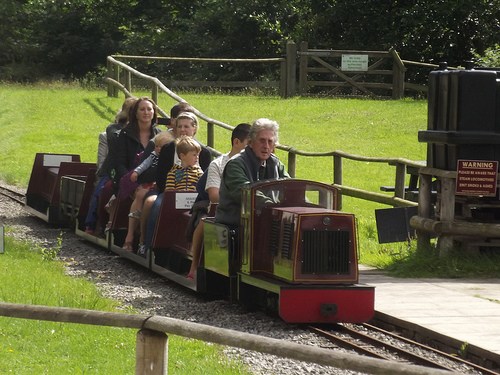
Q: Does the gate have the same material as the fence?
A: Yes, both the gate and the fence are made of wood.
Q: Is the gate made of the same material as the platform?
A: Yes, both the gate and the platform are made of wood.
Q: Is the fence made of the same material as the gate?
A: Yes, both the fence and the gate are made of wood.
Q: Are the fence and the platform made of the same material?
A: Yes, both the fence and the platform are made of wood.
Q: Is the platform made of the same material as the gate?
A: Yes, both the platform and the gate are made of wood.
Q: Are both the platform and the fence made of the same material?
A: Yes, both the platform and the fence are made of wood.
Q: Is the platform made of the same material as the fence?
A: Yes, both the platform and the fence are made of wood.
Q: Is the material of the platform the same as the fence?
A: Yes, both the platform and the fence are made of wood.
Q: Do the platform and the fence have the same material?
A: Yes, both the platform and the fence are made of wood.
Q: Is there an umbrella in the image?
A: No, there are no umbrellas.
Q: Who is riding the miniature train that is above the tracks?
A: The people are riding the train.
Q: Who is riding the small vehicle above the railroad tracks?
A: The people are riding the train.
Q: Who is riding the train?
A: The people are riding the train.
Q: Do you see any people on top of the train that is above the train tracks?
A: Yes, there are people on top of the train.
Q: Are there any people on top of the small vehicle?
A: Yes, there are people on top of the train.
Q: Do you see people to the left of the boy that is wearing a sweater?
A: Yes, there are people to the left of the boy.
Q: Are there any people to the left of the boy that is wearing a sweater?
A: Yes, there are people to the left of the boy.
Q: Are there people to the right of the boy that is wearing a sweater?
A: No, the people are to the left of the boy.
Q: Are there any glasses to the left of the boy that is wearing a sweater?
A: No, there are people to the left of the boy.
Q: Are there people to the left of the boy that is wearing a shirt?
A: Yes, there are people to the left of the boy.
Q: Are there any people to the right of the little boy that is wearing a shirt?
A: No, the people are to the left of the boy.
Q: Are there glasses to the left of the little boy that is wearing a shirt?
A: No, there are people to the left of the boy.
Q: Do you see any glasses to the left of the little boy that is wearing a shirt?
A: No, there are people to the left of the boy.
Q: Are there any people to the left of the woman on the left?
A: Yes, there are people to the left of the woman.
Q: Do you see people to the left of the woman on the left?
A: Yes, there are people to the left of the woman.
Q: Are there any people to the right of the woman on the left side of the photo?
A: No, the people are to the left of the woman.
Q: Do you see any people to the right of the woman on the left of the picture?
A: No, the people are to the left of the woman.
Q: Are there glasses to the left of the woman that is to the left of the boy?
A: No, there are people to the left of the woman.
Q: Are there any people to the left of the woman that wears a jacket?
A: Yes, there are people to the left of the woman.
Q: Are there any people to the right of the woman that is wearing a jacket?
A: No, the people are to the left of the woman.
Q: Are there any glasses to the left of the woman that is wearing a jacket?
A: No, there are people to the left of the woman.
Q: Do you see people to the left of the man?
A: Yes, there are people to the left of the man.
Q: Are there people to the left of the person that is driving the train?
A: Yes, there are people to the left of the man.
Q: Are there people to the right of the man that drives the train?
A: No, the people are to the left of the man.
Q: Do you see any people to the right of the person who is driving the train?
A: No, the people are to the left of the man.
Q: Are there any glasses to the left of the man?
A: No, there are people to the left of the man.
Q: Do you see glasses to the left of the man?
A: No, there are people to the left of the man.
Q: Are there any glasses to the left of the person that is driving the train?
A: No, there are people to the left of the man.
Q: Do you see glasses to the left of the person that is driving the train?
A: No, there are people to the left of the man.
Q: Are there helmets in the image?
A: No, there are no helmets.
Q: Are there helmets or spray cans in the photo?
A: No, there are no helmets or spray cans.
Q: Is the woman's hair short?
A: No, the hair is long.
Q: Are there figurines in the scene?
A: No, there are no figurines.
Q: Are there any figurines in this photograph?
A: No, there are no figurines.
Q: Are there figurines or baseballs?
A: No, there are no figurines or baseballs.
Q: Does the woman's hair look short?
A: Yes, the hair is short.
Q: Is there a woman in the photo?
A: Yes, there is a woman.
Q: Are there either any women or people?
A: Yes, there is a woman.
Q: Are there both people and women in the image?
A: Yes, there are both a woman and people.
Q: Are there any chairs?
A: No, there are no chairs.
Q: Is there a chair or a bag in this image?
A: No, there are no chairs or bags.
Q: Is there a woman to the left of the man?
A: Yes, there is a woman to the left of the man.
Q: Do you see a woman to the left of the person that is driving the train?
A: Yes, there is a woman to the left of the man.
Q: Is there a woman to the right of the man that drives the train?
A: No, the woman is to the left of the man.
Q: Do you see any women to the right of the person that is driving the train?
A: No, the woman is to the left of the man.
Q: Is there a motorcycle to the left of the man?
A: No, there is a woman to the left of the man.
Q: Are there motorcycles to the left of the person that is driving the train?
A: No, there is a woman to the left of the man.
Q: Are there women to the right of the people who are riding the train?
A: Yes, there is a woman to the right of the people.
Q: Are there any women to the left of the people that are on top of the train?
A: No, the woman is to the right of the people.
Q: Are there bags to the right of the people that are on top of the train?
A: No, there is a woman to the right of the people.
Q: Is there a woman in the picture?
A: Yes, there is a woman.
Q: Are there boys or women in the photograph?
A: Yes, there is a woman.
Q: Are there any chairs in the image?
A: No, there are no chairs.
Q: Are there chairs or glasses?
A: No, there are no chairs or glasses.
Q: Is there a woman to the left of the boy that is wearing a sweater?
A: Yes, there is a woman to the left of the boy.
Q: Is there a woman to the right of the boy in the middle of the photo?
A: No, the woman is to the left of the boy.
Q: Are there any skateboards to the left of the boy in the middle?
A: No, there is a woman to the left of the boy.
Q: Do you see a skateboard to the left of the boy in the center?
A: No, there is a woman to the left of the boy.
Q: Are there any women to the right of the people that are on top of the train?
A: Yes, there is a woman to the right of the people.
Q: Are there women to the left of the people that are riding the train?
A: No, the woman is to the right of the people.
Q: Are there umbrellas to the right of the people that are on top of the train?
A: No, there is a woman to the right of the people.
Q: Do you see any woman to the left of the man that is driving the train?
A: Yes, there is a woman to the left of the man.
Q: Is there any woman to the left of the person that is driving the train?
A: Yes, there is a woman to the left of the man.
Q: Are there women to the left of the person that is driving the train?
A: Yes, there is a woman to the left of the man.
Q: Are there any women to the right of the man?
A: No, the woman is to the left of the man.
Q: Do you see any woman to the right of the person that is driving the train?
A: No, the woman is to the left of the man.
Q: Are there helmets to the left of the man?
A: No, there is a woman to the left of the man.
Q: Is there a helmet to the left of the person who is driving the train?
A: No, there is a woman to the left of the man.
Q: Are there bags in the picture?
A: No, there are no bags.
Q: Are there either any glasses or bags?
A: No, there are no bags or glasses.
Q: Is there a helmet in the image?
A: No, there are no helmets.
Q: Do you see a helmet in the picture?
A: No, there are no helmets.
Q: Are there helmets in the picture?
A: No, there are no helmets.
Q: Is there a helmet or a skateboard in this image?
A: No, there are no helmets or skateboards.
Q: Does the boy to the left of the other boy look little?
A: Yes, the boy is little.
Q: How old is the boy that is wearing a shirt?
A: The boy is little.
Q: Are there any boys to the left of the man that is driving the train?
A: Yes, there is a boy to the left of the man.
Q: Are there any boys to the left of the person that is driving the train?
A: Yes, there is a boy to the left of the man.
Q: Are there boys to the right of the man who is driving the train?
A: No, the boy is to the left of the man.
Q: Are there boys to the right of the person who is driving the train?
A: No, the boy is to the left of the man.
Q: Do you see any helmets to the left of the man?
A: No, there is a boy to the left of the man.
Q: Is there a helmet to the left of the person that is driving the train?
A: No, there is a boy to the left of the man.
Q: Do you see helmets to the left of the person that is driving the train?
A: No, there is a boy to the left of the man.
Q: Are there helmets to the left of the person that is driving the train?
A: No, there is a boy to the left of the man.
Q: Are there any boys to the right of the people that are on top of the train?
A: Yes, there is a boy to the right of the people.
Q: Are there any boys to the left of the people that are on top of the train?
A: No, the boy is to the right of the people.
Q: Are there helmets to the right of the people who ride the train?
A: No, there is a boy to the right of the people.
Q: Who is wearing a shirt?
A: The boy is wearing a shirt.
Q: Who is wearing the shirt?
A: The boy is wearing a shirt.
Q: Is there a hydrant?
A: No, there are no fire hydrants.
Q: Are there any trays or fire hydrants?
A: No, there are no fire hydrants or trays.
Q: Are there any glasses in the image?
A: No, there are no glasses.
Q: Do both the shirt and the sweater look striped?
A: Yes, both the shirt and the sweater are striped.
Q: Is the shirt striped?
A: Yes, the shirt is striped.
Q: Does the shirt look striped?
A: Yes, the shirt is striped.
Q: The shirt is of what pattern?
A: The shirt is striped.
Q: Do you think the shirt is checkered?
A: No, the shirt is striped.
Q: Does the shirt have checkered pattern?
A: No, the shirt is striped.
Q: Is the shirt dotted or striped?
A: The shirt is striped.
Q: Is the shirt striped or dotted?
A: The shirt is striped.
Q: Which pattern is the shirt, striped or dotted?
A: The shirt is striped.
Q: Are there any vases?
A: No, there are no vases.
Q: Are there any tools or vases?
A: No, there are no vases or tools.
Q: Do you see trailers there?
A: No, there are no trailers.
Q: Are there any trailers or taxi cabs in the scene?
A: No, there are no trailers or taxi cabs.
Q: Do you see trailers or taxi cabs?
A: No, there are no trailers or taxi cabs.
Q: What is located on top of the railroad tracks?
A: The engine is on top of the railroad tracks.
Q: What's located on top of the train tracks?
A: The engine is on top of the railroad tracks.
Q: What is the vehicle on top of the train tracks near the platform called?
A: The vehicle is a locomotive.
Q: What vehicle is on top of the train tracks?
A: The vehicle is a locomotive.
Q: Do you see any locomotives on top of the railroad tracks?
A: Yes, there is a locomotive on top of the railroad tracks.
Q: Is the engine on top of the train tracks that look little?
A: Yes, the engine is on top of the tracks.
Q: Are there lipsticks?
A: No, there are no lipsticks.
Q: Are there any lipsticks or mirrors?
A: No, there are no lipsticks or mirrors.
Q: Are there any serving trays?
A: No, there are no serving trays.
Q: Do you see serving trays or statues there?
A: No, there are no serving trays or statues.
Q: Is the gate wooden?
A: Yes, the gate is wooden.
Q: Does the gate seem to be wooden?
A: Yes, the gate is wooden.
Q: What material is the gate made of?
A: The gate is made of wood.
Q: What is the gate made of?
A: The gate is made of wood.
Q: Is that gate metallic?
A: No, the gate is wooden.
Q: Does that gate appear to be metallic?
A: No, the gate is wooden.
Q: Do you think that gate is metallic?
A: No, the gate is wooden.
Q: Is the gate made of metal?
A: No, the gate is made of wood.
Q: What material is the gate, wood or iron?
A: The gate is made of wood.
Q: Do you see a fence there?
A: Yes, there is a fence.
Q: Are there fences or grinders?
A: Yes, there is a fence.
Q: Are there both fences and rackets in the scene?
A: No, there is a fence but no rackets.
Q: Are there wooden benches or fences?
A: Yes, there is a wood fence.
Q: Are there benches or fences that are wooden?
A: Yes, the fence is wooden.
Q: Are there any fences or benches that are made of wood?
A: Yes, the fence is made of wood.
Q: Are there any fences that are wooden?
A: Yes, there is a wood fence.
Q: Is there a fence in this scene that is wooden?
A: Yes, there is a fence that is wooden.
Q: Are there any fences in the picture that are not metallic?
A: Yes, there is a wooden fence.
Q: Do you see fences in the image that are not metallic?
A: Yes, there is a wooden fence.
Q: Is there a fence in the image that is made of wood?
A: Yes, there is a fence that is made of wood.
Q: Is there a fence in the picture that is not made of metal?
A: Yes, there is a fence that is made of wood.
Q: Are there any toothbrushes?
A: No, there are no toothbrushes.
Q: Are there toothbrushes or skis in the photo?
A: No, there are no toothbrushes or skis.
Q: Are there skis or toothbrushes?
A: No, there are no toothbrushes or skis.